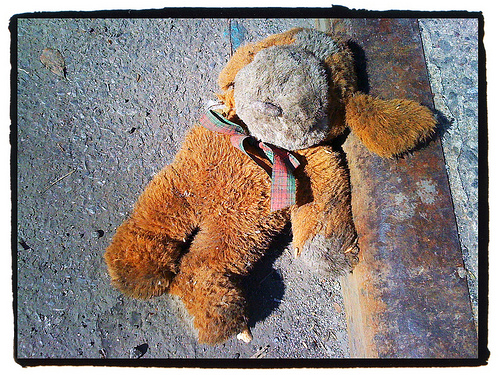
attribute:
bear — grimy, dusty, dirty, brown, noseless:
[99, 24, 429, 346]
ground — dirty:
[16, 16, 480, 362]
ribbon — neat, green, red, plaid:
[195, 100, 304, 213]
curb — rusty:
[330, 19, 480, 369]